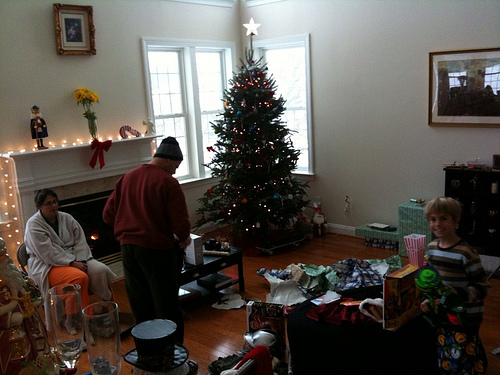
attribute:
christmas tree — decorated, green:
[191, 11, 332, 246]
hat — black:
[152, 136, 183, 165]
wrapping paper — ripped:
[265, 246, 401, 298]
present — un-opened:
[351, 215, 399, 248]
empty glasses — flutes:
[38, 281, 135, 375]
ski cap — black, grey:
[143, 136, 198, 169]